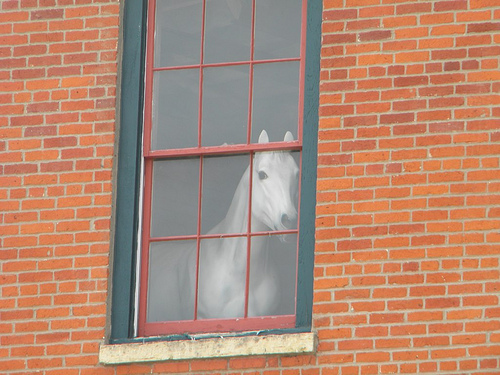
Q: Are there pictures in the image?
A: No, there are no pictures.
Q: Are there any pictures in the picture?
A: No, there are no pictures.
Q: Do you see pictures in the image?
A: No, there are no pictures.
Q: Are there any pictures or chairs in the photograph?
A: No, there are no pictures or chairs.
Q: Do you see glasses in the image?
A: No, there are no glasses.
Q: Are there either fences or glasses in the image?
A: No, there are no glasses or fences.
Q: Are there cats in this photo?
A: No, there are no cats.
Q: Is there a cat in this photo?
A: No, there are no cats.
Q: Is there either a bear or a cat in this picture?
A: No, there are no cats or bears.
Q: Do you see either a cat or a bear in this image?
A: No, there are no cats or bears.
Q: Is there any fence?
A: No, there are no fences.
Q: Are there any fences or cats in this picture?
A: No, there are no fences or cats.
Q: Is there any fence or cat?
A: No, there are no fences or cats.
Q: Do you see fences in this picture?
A: No, there are no fences.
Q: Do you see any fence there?
A: No, there are no fences.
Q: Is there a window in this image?
A: Yes, there is a window.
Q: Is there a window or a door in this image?
A: Yes, there is a window.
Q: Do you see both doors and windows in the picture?
A: No, there is a window but no doors.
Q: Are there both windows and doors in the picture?
A: No, there is a window but no doors.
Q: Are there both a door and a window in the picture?
A: No, there is a window but no doors.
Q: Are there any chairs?
A: No, there are no chairs.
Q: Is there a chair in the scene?
A: No, there are no chairs.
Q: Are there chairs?
A: No, there are no chairs.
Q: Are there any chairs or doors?
A: No, there are no chairs or doors.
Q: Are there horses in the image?
A: Yes, there is a horse.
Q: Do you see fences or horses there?
A: Yes, there is a horse.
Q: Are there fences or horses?
A: Yes, there is a horse.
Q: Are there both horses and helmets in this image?
A: No, there is a horse but no helmets.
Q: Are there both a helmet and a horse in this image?
A: No, there is a horse but no helmets.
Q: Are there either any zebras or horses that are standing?
A: Yes, the horse is standing.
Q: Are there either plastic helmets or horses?
A: Yes, there is a plastic horse.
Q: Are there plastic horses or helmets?
A: Yes, there is a plastic horse.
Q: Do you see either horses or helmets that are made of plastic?
A: Yes, the horse is made of plastic.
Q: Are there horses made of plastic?
A: Yes, there is a horse that is made of plastic.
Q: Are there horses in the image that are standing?
A: Yes, there is a horse that is standing.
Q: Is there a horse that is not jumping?
A: Yes, there is a horse that is standing.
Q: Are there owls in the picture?
A: No, there are no owls.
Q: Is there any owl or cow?
A: No, there are no owls or cows.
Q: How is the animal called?
A: The animal is a horse.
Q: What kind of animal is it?
A: The animal is a horse.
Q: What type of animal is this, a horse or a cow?
A: This is a horse.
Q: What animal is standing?
A: The animal is a horse.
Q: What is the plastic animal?
A: The animal is a horse.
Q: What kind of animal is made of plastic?
A: The animal is a horse.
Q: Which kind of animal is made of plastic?
A: The animal is a horse.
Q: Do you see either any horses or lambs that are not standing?
A: No, there is a horse but it is standing.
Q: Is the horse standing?
A: Yes, the horse is standing.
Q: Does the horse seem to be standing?
A: Yes, the horse is standing.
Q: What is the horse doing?
A: The horse is standing.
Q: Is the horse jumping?
A: No, the horse is standing.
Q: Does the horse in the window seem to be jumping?
A: No, the horse is standing.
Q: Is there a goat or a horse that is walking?
A: No, there is a horse but it is standing.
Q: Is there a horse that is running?
A: No, there is a horse but it is standing.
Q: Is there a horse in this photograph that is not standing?
A: No, there is a horse but it is standing.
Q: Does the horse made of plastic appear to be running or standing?
A: The horse is standing.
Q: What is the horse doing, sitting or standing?
A: The horse is standing.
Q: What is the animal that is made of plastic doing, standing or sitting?
A: The horse is standing.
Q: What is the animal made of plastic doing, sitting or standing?
A: The horse is standing.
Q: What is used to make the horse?
A: The horse is made of plastic.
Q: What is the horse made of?
A: The horse is made of plastic.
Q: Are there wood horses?
A: No, there is a horse but it is made of plastic.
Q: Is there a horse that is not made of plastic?
A: No, there is a horse but it is made of plastic.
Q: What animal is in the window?
A: The horse is in the window.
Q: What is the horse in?
A: The horse is in the window.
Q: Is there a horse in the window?
A: Yes, there is a horse in the window.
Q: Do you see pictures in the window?
A: No, there is a horse in the window.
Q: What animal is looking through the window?
A: The horse is looking through the window.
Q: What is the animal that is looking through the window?
A: The animal is a horse.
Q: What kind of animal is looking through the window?
A: The animal is a horse.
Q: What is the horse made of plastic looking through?
A: The horse is looking through the window.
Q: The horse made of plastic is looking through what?
A: The horse is looking through the window.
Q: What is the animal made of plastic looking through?
A: The horse is looking through the window.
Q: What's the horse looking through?
A: The horse is looking through the window.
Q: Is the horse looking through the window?
A: Yes, the horse is looking through the window.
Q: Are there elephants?
A: No, there are no elephants.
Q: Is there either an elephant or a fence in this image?
A: No, there are no elephants or fences.